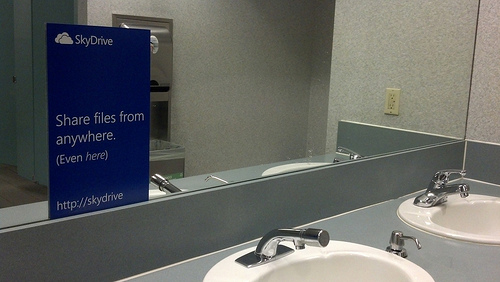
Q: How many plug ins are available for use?
A: Two.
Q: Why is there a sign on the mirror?
A: Advertisement.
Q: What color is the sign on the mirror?
A: Blue.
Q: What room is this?
A: Bathroom.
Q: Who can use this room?
A: Public.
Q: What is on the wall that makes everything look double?
A: Mirror.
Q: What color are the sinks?
A: White.